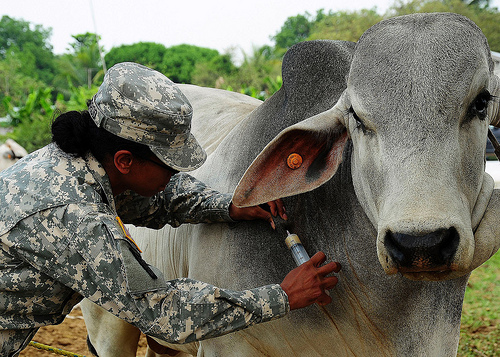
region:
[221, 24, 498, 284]
the head of a cow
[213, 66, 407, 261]
the ear of a cow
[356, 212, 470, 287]
the nose of a cow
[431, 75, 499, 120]
the eye of a cow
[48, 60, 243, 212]
the head of a woman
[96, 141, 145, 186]
the ear of a woman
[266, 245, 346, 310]
the hand of a woman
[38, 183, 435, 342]
the arm of a woman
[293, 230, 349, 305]
the fingers of a woman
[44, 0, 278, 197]
a woman wearing a hat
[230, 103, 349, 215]
the ear of a very large cow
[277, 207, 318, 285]
a very large needle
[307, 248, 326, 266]
the finger of a hand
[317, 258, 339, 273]
the finger of a hand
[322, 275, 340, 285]
the finger of a hand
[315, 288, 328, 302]
the finger of a hand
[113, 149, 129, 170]
the ear of a woman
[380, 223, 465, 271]
the snout of a cow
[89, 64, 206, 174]
the hat on a head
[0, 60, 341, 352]
woman next to cow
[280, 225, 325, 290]
woman is holding a large syringe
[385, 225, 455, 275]
big black leathery nose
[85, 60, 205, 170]
woman wearing a camouflage cap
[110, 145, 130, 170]
ear visible under hat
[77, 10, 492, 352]
big gray cow next to woman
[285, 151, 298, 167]
round orange stud in ear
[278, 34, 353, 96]
gray hump behind head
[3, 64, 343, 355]
woman is injecting the cow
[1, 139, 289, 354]
woman wearing a camouflage jacket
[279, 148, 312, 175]
cow with a tag on its ear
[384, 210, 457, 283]
cow with a black nose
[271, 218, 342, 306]
needle in a cow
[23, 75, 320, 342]
woman wearing a army uniform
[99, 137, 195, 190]
woman with glasses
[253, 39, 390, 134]
cow with a hump on its back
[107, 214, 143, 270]
patch on the unifrom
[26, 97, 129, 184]
woman with a ponytail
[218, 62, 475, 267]
cow with grey skin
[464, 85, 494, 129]
cow with black eyes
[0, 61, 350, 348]
she is giving the animal a shot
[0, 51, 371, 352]
she is wearing camoflage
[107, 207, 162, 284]
a badge on her shirt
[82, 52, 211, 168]
she is wearing a camoflage hat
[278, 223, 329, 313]
her hand is holding the tube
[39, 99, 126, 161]
her hair is black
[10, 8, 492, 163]
trees behind the animal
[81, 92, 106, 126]
her name tag on the back of the hat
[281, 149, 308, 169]
an orange piece in his ear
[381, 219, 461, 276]
his nose is black